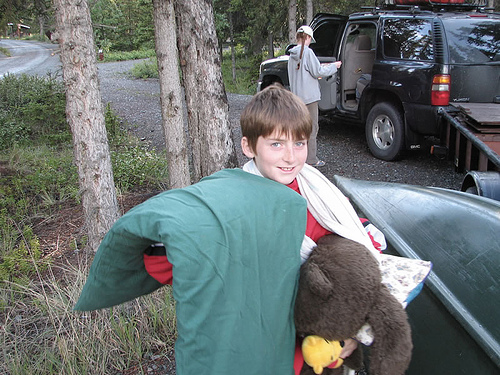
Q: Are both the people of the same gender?
A: No, they are both male and female.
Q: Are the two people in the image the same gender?
A: No, they are both male and female.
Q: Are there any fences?
A: No, there are no fences.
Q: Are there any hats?
A: Yes, there is a hat.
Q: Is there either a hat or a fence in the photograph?
A: Yes, there is a hat.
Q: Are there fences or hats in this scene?
A: Yes, there is a hat.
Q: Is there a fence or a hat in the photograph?
A: Yes, there is a hat.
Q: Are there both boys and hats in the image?
A: Yes, there are both a hat and a boy.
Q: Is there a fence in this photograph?
A: No, there are no fences.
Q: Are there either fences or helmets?
A: No, there are no fences or helmets.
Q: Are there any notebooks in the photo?
A: No, there are no notebooks.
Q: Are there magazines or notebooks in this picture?
A: No, there are no notebooks or magazines.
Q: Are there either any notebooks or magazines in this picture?
A: No, there are no notebooks or magazines.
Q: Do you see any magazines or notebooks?
A: No, there are no notebooks or magazines.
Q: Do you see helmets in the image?
A: No, there are no helmets.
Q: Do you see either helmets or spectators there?
A: No, there are no helmets or spectators.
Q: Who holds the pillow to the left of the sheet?
A: The boy holds the pillow.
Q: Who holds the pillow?
A: The boy holds the pillow.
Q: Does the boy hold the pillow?
A: Yes, the boy holds the pillow.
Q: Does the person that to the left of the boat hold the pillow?
A: Yes, the boy holds the pillow.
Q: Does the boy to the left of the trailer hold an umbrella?
A: No, the boy holds the pillow.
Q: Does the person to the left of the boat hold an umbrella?
A: No, the boy holds the pillow.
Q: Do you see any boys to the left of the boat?
A: Yes, there is a boy to the left of the boat.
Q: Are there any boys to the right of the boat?
A: No, the boy is to the left of the boat.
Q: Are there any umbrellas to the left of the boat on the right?
A: No, there is a boy to the left of the boat.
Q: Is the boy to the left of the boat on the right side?
A: Yes, the boy is to the left of the boat.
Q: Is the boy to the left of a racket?
A: No, the boy is to the left of the boat.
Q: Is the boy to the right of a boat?
A: No, the boy is to the left of a boat.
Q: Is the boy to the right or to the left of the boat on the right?
A: The boy is to the left of the boat.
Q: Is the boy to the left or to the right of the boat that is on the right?
A: The boy is to the left of the boat.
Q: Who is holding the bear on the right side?
A: The boy is holding the bear.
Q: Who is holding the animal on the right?
A: The boy is holding the bear.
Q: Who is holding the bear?
A: The boy is holding the bear.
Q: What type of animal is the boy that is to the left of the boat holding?
A: The boy is holding the bear.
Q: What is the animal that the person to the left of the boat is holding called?
A: The animal is a bear.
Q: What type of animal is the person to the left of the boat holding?
A: The boy is holding the bear.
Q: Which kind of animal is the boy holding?
A: The boy is holding the bear.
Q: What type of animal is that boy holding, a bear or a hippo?
A: The boy is holding a bear.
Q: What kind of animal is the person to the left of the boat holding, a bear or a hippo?
A: The boy is holding a bear.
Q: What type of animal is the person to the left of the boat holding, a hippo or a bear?
A: The boy is holding a bear.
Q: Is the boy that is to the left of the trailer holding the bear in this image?
A: Yes, the boy is holding the bear.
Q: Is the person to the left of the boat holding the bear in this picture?
A: Yes, the boy is holding the bear.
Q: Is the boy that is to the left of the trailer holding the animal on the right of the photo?
A: Yes, the boy is holding the bear.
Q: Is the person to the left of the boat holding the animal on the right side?
A: Yes, the boy is holding the bear.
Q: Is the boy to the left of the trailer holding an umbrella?
A: No, the boy is holding the bear.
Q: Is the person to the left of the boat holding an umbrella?
A: No, the boy is holding the bear.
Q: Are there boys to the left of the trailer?
A: Yes, there is a boy to the left of the trailer.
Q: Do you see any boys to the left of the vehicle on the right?
A: Yes, there is a boy to the left of the trailer.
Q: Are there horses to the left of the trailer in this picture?
A: No, there is a boy to the left of the trailer.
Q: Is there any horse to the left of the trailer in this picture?
A: No, there is a boy to the left of the trailer.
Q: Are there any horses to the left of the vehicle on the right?
A: No, there is a boy to the left of the trailer.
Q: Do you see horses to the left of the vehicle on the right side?
A: No, there is a boy to the left of the trailer.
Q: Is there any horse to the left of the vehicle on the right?
A: No, there is a boy to the left of the trailer.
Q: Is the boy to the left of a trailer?
A: Yes, the boy is to the left of a trailer.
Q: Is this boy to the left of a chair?
A: No, the boy is to the left of a trailer.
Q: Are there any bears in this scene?
A: Yes, there is a bear.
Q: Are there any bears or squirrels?
A: Yes, there is a bear.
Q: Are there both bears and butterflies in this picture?
A: No, there is a bear but no butterflies.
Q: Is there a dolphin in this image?
A: No, there are no dolphins.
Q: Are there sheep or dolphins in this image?
A: No, there are no dolphins or sheep.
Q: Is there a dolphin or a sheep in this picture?
A: No, there are no dolphins or sheep.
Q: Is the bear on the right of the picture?
A: Yes, the bear is on the right of the image.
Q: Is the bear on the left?
A: No, the bear is on the right of the image.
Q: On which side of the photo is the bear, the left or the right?
A: The bear is on the right of the image.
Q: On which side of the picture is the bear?
A: The bear is on the right of the image.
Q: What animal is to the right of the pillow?
A: The animal is a bear.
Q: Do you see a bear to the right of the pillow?
A: Yes, there is a bear to the right of the pillow.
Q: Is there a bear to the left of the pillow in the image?
A: No, the bear is to the right of the pillow.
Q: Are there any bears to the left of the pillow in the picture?
A: No, the bear is to the right of the pillow.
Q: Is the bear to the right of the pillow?
A: Yes, the bear is to the right of the pillow.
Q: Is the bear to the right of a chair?
A: No, the bear is to the right of the pillow.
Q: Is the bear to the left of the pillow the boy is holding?
A: No, the bear is to the right of the pillow.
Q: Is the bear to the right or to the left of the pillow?
A: The bear is to the right of the pillow.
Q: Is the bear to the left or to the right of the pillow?
A: The bear is to the right of the pillow.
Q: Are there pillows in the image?
A: Yes, there is a pillow.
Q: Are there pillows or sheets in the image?
A: Yes, there is a pillow.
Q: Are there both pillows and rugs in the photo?
A: No, there is a pillow but no rugs.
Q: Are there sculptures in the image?
A: No, there are no sculptures.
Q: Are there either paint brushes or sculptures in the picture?
A: No, there are no sculptures or paint brushes.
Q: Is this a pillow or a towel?
A: This is a pillow.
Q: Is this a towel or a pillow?
A: This is a pillow.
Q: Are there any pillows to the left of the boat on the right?
A: Yes, there is a pillow to the left of the boat.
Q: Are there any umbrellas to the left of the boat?
A: No, there is a pillow to the left of the boat.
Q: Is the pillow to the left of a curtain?
A: No, the pillow is to the left of a boat.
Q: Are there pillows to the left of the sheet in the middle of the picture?
A: Yes, there is a pillow to the left of the bed sheet.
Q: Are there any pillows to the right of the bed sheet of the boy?
A: No, the pillow is to the left of the bed sheet.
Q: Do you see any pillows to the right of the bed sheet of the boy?
A: No, the pillow is to the left of the bed sheet.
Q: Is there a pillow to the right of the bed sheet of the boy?
A: No, the pillow is to the left of the bed sheet.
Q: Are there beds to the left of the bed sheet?
A: No, there is a pillow to the left of the bed sheet.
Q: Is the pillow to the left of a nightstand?
A: No, the pillow is to the left of a sheet.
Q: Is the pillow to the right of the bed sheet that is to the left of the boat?
A: No, the pillow is to the left of the sheet.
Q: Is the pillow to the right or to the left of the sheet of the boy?
A: The pillow is to the left of the bed sheet.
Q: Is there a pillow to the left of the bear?
A: Yes, there is a pillow to the left of the bear.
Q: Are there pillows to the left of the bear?
A: Yes, there is a pillow to the left of the bear.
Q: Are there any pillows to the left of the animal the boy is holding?
A: Yes, there is a pillow to the left of the bear.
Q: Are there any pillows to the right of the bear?
A: No, the pillow is to the left of the bear.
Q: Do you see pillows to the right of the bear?
A: No, the pillow is to the left of the bear.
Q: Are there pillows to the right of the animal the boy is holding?
A: No, the pillow is to the left of the bear.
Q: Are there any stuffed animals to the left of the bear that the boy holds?
A: No, there is a pillow to the left of the bear.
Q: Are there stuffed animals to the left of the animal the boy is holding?
A: No, there is a pillow to the left of the bear.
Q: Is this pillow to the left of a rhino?
A: No, the pillow is to the left of a bear.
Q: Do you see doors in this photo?
A: Yes, there is a door.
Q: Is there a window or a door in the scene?
A: Yes, there is a door.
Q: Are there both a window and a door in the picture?
A: Yes, there are both a door and a window.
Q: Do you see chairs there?
A: No, there are no chairs.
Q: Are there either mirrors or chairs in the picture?
A: No, there are no chairs or mirrors.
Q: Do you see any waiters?
A: No, there are no waiters.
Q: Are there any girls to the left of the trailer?
A: Yes, there is a girl to the left of the trailer.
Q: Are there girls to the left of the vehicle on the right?
A: Yes, there is a girl to the left of the trailer.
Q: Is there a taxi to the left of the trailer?
A: No, there is a girl to the left of the trailer.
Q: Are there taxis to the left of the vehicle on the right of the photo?
A: No, there is a girl to the left of the trailer.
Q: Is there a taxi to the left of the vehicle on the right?
A: No, there is a girl to the left of the trailer.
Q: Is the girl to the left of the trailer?
A: Yes, the girl is to the left of the trailer.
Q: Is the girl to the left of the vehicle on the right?
A: Yes, the girl is to the left of the trailer.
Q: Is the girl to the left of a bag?
A: No, the girl is to the left of the trailer.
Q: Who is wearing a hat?
A: The girl is wearing a hat.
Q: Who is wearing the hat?
A: The girl is wearing a hat.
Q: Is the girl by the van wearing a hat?
A: Yes, the girl is wearing a hat.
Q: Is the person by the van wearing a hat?
A: Yes, the girl is wearing a hat.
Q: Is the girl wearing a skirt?
A: No, the girl is wearing a hat.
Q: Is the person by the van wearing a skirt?
A: No, the girl is wearing a hat.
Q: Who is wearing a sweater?
A: The girl is wearing a sweater.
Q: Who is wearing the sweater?
A: The girl is wearing a sweater.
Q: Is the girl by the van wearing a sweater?
A: Yes, the girl is wearing a sweater.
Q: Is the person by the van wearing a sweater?
A: Yes, the girl is wearing a sweater.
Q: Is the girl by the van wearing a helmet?
A: No, the girl is wearing a sweater.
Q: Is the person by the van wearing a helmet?
A: No, the girl is wearing a sweater.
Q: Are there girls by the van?
A: Yes, there is a girl by the van.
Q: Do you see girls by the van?
A: Yes, there is a girl by the van.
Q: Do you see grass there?
A: Yes, there is grass.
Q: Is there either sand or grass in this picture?
A: Yes, there is grass.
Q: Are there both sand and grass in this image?
A: No, there is grass but no sand.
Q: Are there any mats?
A: No, there are no mats.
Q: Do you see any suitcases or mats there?
A: No, there are no mats or suitcases.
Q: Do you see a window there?
A: Yes, there are windows.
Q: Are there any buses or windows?
A: Yes, there are windows.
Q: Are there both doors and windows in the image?
A: Yes, there are both windows and a door.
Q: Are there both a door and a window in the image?
A: Yes, there are both a window and a door.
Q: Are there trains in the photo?
A: No, there are no trains.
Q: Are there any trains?
A: No, there are no trains.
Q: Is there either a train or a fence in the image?
A: No, there are no trains or fences.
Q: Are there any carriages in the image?
A: No, there are no carriages.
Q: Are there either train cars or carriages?
A: No, there are no carriages or train cars.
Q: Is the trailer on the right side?
A: Yes, the trailer is on the right of the image.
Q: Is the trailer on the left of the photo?
A: No, the trailer is on the right of the image.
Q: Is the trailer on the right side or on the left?
A: The trailer is on the right of the image.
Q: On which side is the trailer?
A: The trailer is on the right of the image.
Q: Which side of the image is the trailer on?
A: The trailer is on the right of the image.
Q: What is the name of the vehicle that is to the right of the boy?
A: The vehicle is a trailer.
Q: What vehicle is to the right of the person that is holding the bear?
A: The vehicle is a trailer.